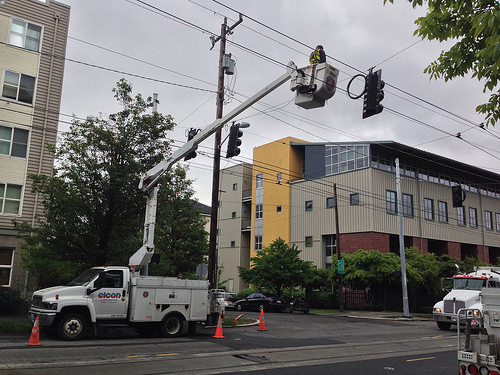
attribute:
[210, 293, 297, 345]
cones — orange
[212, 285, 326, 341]
car — black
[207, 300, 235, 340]
cone — orange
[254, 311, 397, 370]
pavement — smooth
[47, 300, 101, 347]
tire — black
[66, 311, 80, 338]
hub cap — white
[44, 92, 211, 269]
tree — green leaves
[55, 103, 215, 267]
tree — green leaves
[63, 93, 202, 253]
tree — green leaves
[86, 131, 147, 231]
tree — green leaves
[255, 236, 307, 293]
tree — green leaves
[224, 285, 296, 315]
car — parked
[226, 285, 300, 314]
car — parked